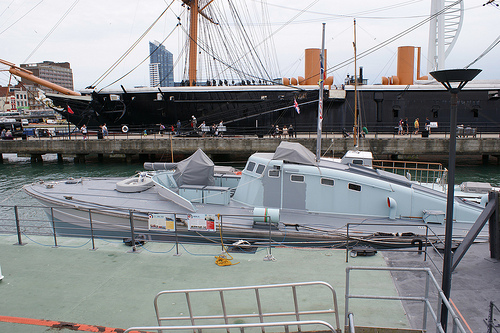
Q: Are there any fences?
A: Yes, there is a fence.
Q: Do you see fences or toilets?
A: Yes, there is a fence.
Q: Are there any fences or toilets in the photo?
A: Yes, there is a fence.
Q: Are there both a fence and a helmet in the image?
A: No, there is a fence but no helmets.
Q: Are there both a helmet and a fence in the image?
A: No, there is a fence but no helmets.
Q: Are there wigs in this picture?
A: No, there are no wigs.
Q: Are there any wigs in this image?
A: No, there are no wigs.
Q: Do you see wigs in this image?
A: No, there are no wigs.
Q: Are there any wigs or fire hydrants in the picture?
A: No, there are no wigs or fire hydrants.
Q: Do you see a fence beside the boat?
A: Yes, there is a fence beside the boat.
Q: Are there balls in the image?
A: No, there are no balls.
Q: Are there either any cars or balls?
A: No, there are no balls or cars.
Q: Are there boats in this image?
A: Yes, there is a boat.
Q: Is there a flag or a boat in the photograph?
A: Yes, there is a boat.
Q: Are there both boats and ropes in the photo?
A: Yes, there are both a boat and a rope.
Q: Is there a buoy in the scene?
A: No, there are no buoys.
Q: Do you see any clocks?
A: No, there are no clocks.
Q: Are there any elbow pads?
A: No, there are no elbow pads.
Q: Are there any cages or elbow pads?
A: No, there are no elbow pads or cages.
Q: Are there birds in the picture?
A: No, there are no birds.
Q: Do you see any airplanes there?
A: No, there are no airplanes.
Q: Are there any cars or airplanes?
A: No, there are no airplanes or cars.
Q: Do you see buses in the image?
A: No, there are no buses.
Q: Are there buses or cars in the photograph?
A: No, there are no buses or cars.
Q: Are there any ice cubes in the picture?
A: No, there are no ice cubes.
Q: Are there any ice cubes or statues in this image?
A: No, there are no ice cubes or statues.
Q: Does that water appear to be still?
A: Yes, the water is still.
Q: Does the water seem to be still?
A: Yes, the water is still.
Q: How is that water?
A: The water is still.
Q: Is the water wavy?
A: No, the water is still.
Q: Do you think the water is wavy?
A: No, the water is still.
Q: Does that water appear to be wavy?
A: No, the water is still.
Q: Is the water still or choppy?
A: The water is still.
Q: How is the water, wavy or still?
A: The water is still.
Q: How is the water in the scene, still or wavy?
A: The water is still.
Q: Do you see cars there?
A: No, there are no cars.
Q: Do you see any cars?
A: No, there are no cars.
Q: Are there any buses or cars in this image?
A: No, there are no cars or buses.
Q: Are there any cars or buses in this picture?
A: No, there are no cars or buses.